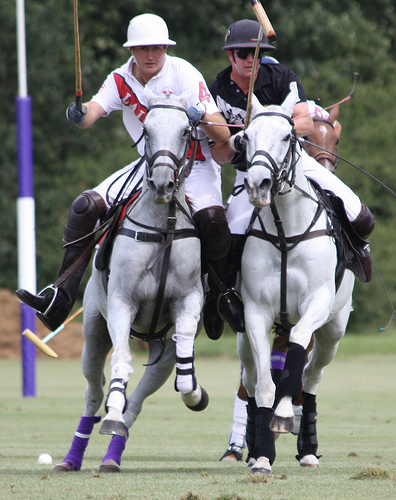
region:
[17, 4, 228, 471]
Polo player on a horse.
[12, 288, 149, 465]
Identifying color on pole and horse.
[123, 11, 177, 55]
White hat on player.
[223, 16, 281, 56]
Black hat on a player.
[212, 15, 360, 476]
Polo player playing polo.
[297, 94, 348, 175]
Horse in the background.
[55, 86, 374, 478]
Horses that riders are riding.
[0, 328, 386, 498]
Green area that players are on.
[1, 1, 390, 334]
Trees in the background.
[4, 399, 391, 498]
Divets in the ground where it is dug up.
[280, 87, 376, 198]
one brown horse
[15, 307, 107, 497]
trying to hit the ball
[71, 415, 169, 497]
blue wrap on the horse's hoofs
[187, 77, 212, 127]
number 4 on his jersey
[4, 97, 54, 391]
white and blue pole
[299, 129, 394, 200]
crop used to move horse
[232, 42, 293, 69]
man is wearing sunglasses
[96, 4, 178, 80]
man wearing a white helmet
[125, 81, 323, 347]
two white horses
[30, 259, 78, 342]
boot in the stirup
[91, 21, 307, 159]
two people racing their animals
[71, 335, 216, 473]
hooves of the animals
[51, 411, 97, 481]
sock on the horses leg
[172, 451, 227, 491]
green ground under horses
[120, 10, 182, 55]
hat on man's head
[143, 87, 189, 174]
white horse carrying man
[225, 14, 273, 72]
black helmet and glasses on man's head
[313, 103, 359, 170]
brown horse behind the white ones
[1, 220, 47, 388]
blue and white pole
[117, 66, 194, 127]
red and white shirt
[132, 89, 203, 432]
white horse ridden during polo tournament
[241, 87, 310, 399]
white horse ridden during polo tournament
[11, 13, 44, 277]
white and purple pole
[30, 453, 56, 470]
white ball used during polo tournament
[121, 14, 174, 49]
white helmet worn by player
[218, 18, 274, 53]
black helmet worn by player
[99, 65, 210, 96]
red and white shirt worn by player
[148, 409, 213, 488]
green grass on polo field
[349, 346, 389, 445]
green grass on polo field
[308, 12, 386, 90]
tree with green leaves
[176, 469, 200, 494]
part of a green ground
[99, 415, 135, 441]
edge of a hoof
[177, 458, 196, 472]
part of a shade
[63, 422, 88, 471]
part of a cloth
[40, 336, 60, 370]
edge of a wood